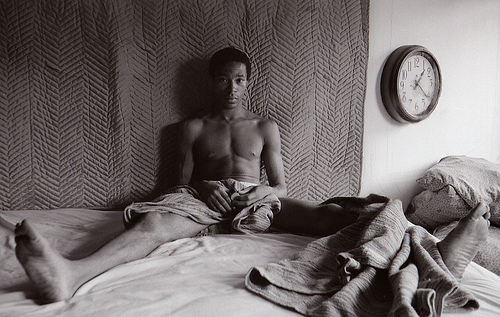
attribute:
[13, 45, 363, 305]
boy — shirtless, young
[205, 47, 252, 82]
hair — black, short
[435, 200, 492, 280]
foot — bare, long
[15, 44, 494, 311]
man — sitting, shirtless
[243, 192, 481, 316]
blankets — pushed off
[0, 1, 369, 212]
back — patterned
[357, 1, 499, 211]
wall — white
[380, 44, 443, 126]
frame — brown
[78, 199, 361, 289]
legs — extended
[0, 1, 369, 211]
blanket — hanging